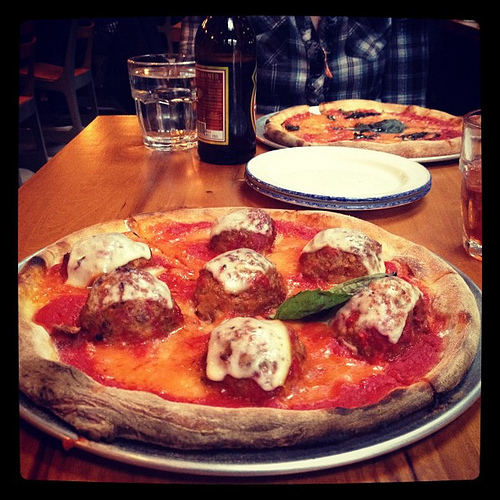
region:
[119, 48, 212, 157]
A GLASS OF WATER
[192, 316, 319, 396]
A MEATBALL WITH CHEESE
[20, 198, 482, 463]
A CHEESE AND MEATBALL PIZZA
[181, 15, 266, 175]
A DARK BOTTLE OF BEER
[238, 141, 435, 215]
A STACK OF PAPER PLATES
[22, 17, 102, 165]
TWO CHAIRS IN THE BACKGROUND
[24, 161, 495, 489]
A BROWN WOODEN TABLE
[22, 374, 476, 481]
A METAL PIZZA TRAY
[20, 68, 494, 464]
TWO PIZZAS ON THE TABLE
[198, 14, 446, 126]
A PERSON SITTING AT THE TABLE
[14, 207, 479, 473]
there are meatballs on the pizza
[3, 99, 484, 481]
two pizzas on the table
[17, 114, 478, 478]
the table is make of wook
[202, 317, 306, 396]
meatball has cheese on it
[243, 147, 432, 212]
the plates have blue edges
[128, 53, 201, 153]
the liquid in the glass is clear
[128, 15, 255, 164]
the glass is next to the bottle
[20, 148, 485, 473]
the plates are next to the pizza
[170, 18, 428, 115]
the shirt is plaid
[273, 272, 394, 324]
the leaf is green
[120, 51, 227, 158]
a glass of water on the end of the table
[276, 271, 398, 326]
green leaf in the pizza dish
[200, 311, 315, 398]
meatball in the pizza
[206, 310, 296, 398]
cheese on the meatball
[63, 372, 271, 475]
pizza crust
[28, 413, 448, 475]
silver plate under the pizza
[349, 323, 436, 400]
tomato sauce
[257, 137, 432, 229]
plates in the middle of the table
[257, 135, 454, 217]
white plates with a blue trim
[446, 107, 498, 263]
a glass containing a brown drink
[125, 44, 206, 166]
Glass cup is on table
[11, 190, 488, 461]
Cooked Pizza in on the table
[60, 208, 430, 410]
Pizza has large meatballs with cheese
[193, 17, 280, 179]
Beer glass is on the table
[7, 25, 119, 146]
Chairs are in the background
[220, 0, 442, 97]
Person is wearing a blue plaid shirt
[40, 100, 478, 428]
Two types of pizzas on are on the table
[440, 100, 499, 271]
Glass has a light brown colored drink inside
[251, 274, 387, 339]
Pizza has a leaf on it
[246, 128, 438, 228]
White Plates are on the table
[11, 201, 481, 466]
A meatball pizza on a pan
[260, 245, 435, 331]
Parsley next to an meatball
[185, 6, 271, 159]
A bottle of alcohol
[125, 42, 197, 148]
A glass of water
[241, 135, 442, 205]
A white dinner plate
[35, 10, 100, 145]
A wooden chair next to another wooden chair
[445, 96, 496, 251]
A glass of beer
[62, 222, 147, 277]
Melted cheese on meatball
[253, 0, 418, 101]
A plaid shirt on a person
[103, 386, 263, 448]
Baked crust on pizza